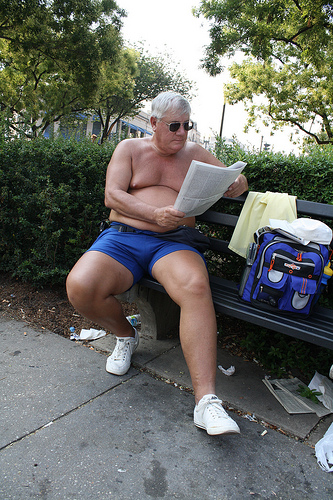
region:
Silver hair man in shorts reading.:
[65, 88, 246, 438]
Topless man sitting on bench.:
[63, 89, 246, 438]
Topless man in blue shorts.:
[65, 90, 240, 438]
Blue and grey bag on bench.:
[235, 223, 331, 318]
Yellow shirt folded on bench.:
[227, 190, 296, 257]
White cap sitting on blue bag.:
[278, 216, 332, 246]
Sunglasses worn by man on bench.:
[153, 114, 197, 133]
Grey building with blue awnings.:
[25, 90, 154, 143]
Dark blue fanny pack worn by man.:
[99, 219, 213, 251]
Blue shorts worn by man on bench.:
[88, 221, 208, 289]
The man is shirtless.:
[120, 135, 207, 222]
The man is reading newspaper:
[95, 124, 256, 227]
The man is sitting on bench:
[80, 179, 303, 323]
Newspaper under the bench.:
[257, 368, 326, 431]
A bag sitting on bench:
[240, 215, 320, 321]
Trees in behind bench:
[33, 31, 148, 154]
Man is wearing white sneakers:
[175, 387, 244, 444]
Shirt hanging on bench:
[242, 179, 282, 245]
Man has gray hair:
[147, 92, 194, 121]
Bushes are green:
[15, 143, 87, 239]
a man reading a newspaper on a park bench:
[64, 90, 249, 438]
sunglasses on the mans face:
[161, 119, 197, 132]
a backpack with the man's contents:
[237, 218, 330, 324]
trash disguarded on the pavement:
[10, 309, 330, 481]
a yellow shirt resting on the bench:
[225, 190, 304, 262]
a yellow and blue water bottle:
[318, 259, 332, 287]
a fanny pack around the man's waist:
[90, 217, 215, 256]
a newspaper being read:
[171, 158, 249, 217]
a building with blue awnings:
[2, 84, 207, 155]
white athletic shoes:
[103, 323, 242, 435]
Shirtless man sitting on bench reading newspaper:
[65, 89, 248, 435]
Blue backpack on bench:
[236, 225, 332, 319]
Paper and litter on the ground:
[219, 358, 331, 420]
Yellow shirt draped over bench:
[225, 190, 299, 259]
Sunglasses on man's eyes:
[149, 90, 195, 152]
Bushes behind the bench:
[0, 138, 332, 284]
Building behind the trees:
[4, 105, 151, 138]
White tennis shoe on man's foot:
[190, 394, 240, 434]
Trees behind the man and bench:
[0, 1, 332, 142]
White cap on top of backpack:
[267, 217, 331, 243]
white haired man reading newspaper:
[60, 57, 226, 321]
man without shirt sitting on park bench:
[94, 82, 236, 314]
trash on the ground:
[219, 335, 330, 472]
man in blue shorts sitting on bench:
[61, 85, 247, 349]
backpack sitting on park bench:
[237, 214, 323, 340]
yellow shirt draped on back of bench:
[224, 169, 300, 261]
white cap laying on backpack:
[262, 202, 332, 264]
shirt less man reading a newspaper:
[85, 80, 252, 245]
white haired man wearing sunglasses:
[138, 85, 208, 159]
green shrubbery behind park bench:
[214, 133, 329, 209]